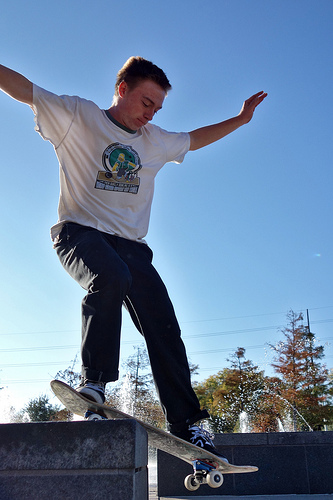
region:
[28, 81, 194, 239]
man wearing white shirt with skateboard logo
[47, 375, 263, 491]
skateboard on edge of wall with white wheels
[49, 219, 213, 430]
black pants worn by skateboarder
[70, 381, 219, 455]
white and black tennis shoes on man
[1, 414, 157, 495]
concrete grey brick wall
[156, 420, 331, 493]
concrete grey brick wall in front of fountain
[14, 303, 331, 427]
green trees in background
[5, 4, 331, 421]
bright blue sunny cloudless sky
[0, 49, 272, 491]
boy jumping off of wall on skateboard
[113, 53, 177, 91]
short military haircut on skateboarder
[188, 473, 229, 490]
wheels on the skateboard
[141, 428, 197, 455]
bottom of the skatebaord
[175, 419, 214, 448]
shoe on the skateboard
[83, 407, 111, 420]
wheel of the skateboard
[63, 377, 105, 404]
foot o nthe skateboard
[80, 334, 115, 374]
pants on the leg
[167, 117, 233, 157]
arm of the man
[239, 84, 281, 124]
hand of the man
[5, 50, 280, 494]
A skateboarder doing a trick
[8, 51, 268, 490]
A skateboarder doing a trick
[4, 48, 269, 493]
A skateboarder doing a trick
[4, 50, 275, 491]
A skateboarder doing a trick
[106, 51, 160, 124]
head of the man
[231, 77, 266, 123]
hand of the man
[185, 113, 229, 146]
arm of the man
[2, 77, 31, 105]
arm of the man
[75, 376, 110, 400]
shoe on the skateboard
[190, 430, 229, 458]
shoe on the skateboard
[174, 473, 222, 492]
wheels of the skateboard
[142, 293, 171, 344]
the pants are black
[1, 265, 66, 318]
the sky is clear